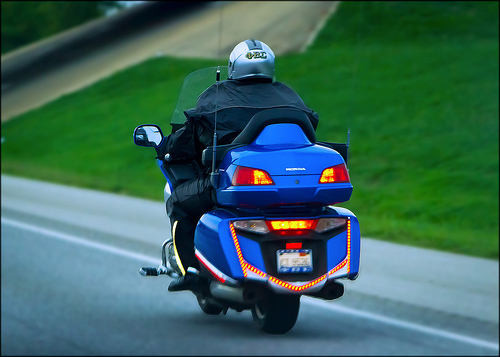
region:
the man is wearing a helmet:
[226, 38, 274, 83]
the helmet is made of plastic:
[226, 39, 276, 79]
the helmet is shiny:
[225, 40, 274, 79]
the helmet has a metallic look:
[228, 38, 275, 79]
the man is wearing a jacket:
[167, 81, 314, 178]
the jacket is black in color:
[164, 76, 323, 201]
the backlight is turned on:
[229, 160, 276, 187]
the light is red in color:
[234, 162, 271, 188]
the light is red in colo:
[318, 162, 350, 184]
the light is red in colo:
[267, 215, 316, 232]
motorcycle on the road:
[152, 24, 392, 344]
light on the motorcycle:
[238, 171, 274, 190]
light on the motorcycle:
[317, 160, 346, 191]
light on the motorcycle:
[274, 220, 321, 237]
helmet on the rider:
[237, 46, 284, 95]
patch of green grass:
[422, 215, 435, 228]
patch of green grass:
[401, 213, 413, 234]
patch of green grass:
[402, 165, 424, 187]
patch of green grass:
[91, 168, 111, 185]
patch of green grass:
[388, 138, 418, 156]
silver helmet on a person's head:
[224, 37, 278, 82]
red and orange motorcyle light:
[228, 165, 276, 188]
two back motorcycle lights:
[228, 161, 353, 187]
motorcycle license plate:
[278, 249, 317, 272]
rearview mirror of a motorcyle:
[130, 124, 167, 149]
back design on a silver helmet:
[244, 50, 269, 60]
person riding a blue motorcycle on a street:
[132, 34, 377, 334]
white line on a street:
[0, 213, 498, 355]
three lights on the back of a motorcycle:
[231, 163, 356, 236]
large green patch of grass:
[0, 2, 497, 259]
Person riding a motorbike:
[128, 34, 365, 338]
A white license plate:
[272, 243, 317, 277]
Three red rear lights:
[228, 154, 353, 235]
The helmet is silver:
[223, 32, 281, 85]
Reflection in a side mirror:
[129, 120, 170, 152]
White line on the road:
[1, 211, 499, 354]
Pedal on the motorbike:
[134, 256, 171, 282]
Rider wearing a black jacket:
[161, 34, 322, 158]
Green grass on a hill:
[2, 3, 499, 262]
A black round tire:
[248, 285, 301, 339]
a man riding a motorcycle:
[129, 39, 361, 330]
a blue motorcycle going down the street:
[119, 123, 376, 333]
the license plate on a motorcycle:
[274, 245, 315, 278]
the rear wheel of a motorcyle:
[240, 283, 302, 335]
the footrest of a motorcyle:
[131, 261, 163, 276]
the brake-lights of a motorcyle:
[223, 160, 349, 192]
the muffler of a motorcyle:
[208, 278, 263, 308]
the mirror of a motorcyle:
[125, 117, 160, 154]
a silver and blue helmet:
[220, 36, 280, 78]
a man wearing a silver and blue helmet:
[178, 35, 326, 174]